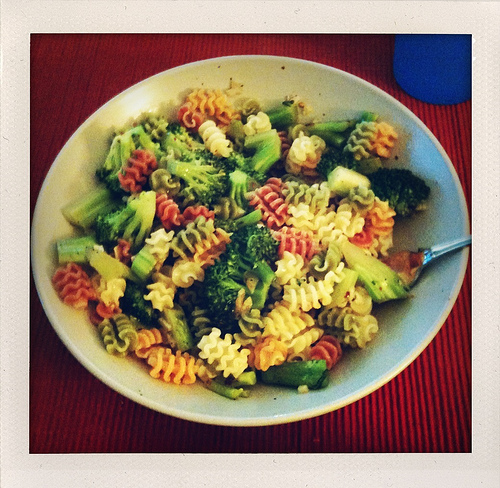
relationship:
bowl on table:
[28, 54, 468, 429] [31, 36, 472, 451]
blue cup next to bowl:
[392, 34, 471, 105] [28, 54, 468, 429]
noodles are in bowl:
[126, 155, 354, 346] [38, 36, 475, 444]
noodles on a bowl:
[50, 77, 398, 385] [29, 54, 471, 427]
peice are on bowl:
[120, 151, 148, 195] [29, 54, 471, 427]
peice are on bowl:
[33, 52, 465, 433] [29, 54, 471, 427]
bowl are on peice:
[29, 54, 471, 427] [120, 151, 148, 195]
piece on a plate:
[341, 118, 397, 164] [28, 52, 470, 430]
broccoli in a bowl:
[54, 92, 449, 384] [59, 60, 459, 426]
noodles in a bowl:
[50, 77, 398, 385] [59, 60, 459, 426]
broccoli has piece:
[371, 167, 433, 224] [372, 161, 446, 231]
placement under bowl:
[381, 383, 464, 443] [29, 54, 471, 427]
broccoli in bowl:
[168, 154, 229, 206] [29, 54, 471, 427]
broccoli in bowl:
[370, 166, 431, 217] [29, 54, 471, 427]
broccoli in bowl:
[205, 222, 283, 324] [29, 54, 471, 427]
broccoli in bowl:
[89, 190, 165, 255] [29, 54, 471, 427]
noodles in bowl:
[50, 77, 398, 385] [29, 54, 471, 427]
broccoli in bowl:
[115, 125, 207, 174] [28, 54, 468, 429]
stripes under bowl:
[402, 375, 456, 440] [29, 54, 471, 427]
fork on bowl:
[379, 235, 472, 291] [28, 54, 468, 429]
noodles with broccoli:
[50, 77, 398, 385] [375, 167, 427, 211]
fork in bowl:
[379, 231, 471, 291] [28, 54, 468, 429]